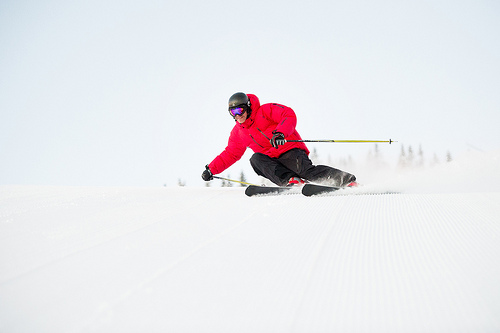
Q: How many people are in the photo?
A: One.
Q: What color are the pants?
A: Black.